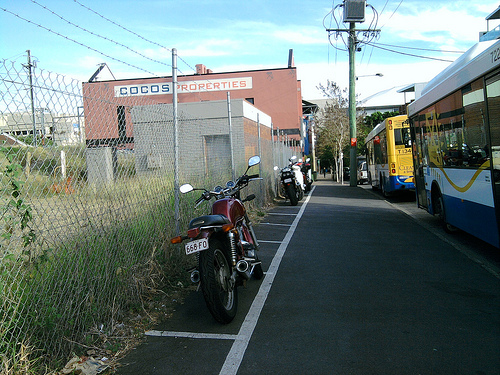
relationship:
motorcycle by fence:
[171, 154, 265, 325] [1, 54, 304, 374]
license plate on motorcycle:
[179, 235, 211, 255] [171, 154, 265, 325]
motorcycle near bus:
[171, 154, 265, 325] [402, 20, 499, 247]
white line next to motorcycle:
[212, 178, 319, 374] [171, 154, 265, 325]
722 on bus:
[488, 48, 499, 69] [402, 20, 499, 247]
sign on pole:
[348, 135, 359, 148] [344, 20, 362, 187]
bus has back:
[361, 112, 415, 195] [382, 111, 414, 184]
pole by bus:
[344, 20, 362, 187] [361, 112, 415, 195]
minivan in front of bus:
[358, 158, 368, 184] [361, 112, 415, 195]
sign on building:
[112, 74, 256, 101] [76, 46, 309, 190]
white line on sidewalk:
[212, 178, 319, 374] [98, 172, 500, 373]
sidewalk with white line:
[98, 172, 500, 373] [212, 178, 319, 374]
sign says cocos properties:
[112, 74, 256, 101] [118, 78, 252, 94]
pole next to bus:
[344, 20, 362, 187] [361, 112, 415, 195]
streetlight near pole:
[350, 69, 386, 83] [344, 20, 362, 187]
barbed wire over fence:
[1, 0, 201, 77] [1, 54, 304, 374]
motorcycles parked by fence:
[279, 151, 315, 207] [1, 54, 304, 374]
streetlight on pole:
[350, 69, 386, 83] [344, 20, 362, 187]